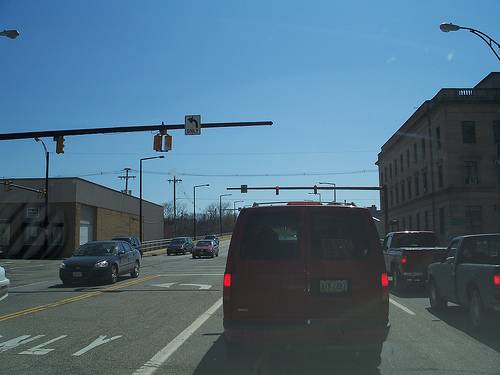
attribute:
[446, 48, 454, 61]
cloud — white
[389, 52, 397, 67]
cloud — white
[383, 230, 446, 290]
truck — pickup truck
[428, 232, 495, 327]
truck — pickup truck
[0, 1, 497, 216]
sky — blue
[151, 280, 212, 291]
arrow — traffic, directional, white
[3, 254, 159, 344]
line — yellow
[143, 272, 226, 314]
arrow — white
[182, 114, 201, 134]
white sign — square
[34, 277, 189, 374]
street — painted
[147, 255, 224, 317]
arrow — white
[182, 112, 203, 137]
sign — white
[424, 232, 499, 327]
truck — white, pick up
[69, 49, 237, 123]
clouds — white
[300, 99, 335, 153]
sky — blue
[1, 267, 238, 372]
lines — white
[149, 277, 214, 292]
arrow — white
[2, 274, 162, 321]
line — Double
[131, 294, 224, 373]
line — painted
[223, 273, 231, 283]
light — on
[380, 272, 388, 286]
light — on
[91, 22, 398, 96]
sky — blue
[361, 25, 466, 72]
clouds — white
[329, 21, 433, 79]
clouds — white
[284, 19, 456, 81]
clouds — white